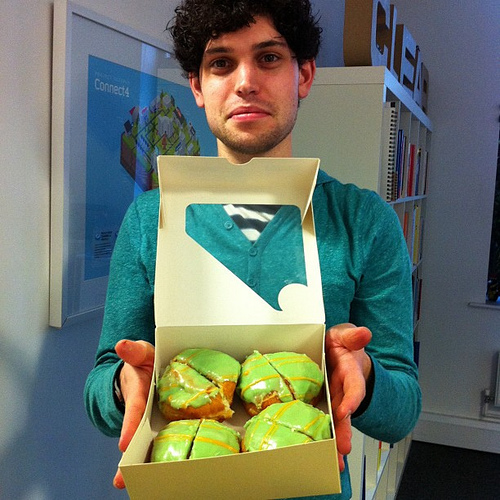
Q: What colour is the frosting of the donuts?
A: Green and yellow.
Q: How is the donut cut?
A: It is cut in half.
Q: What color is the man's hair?
A: Black.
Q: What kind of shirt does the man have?
A: A henley shirt.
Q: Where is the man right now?
A: In a room.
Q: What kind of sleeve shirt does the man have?
A: Long sleeve shirt.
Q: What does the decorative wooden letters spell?
A: CLEAR.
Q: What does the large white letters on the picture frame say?
A: Connect4.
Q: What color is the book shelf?
A: White.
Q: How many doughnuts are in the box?
A: Four.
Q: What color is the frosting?
A: Bright green and yellow.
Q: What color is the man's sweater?
A: Blue.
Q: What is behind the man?
A: White bookshelf.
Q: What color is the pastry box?
A: White.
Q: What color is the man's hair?
A: Black.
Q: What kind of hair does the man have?
A: Curly.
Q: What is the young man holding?
A: White box.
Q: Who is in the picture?
A: A man.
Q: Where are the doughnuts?
A: In a box.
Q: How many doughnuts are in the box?
A: 4.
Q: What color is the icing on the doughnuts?
A: Green.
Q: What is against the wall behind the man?
A: A shelf.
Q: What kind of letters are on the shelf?
A: Wooden.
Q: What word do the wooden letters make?
A: Clear.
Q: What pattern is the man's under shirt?
A: Stripes.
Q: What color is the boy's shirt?
A: Blue.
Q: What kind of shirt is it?
A: Cardigan.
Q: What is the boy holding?
A: Donuts.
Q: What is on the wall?
A: Pictures.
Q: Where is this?
A: Living room.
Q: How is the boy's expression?
A: Smile.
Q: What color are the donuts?
A: Green.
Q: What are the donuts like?
A: Sliced.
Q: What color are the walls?
A: White.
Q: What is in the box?
A: Donuts.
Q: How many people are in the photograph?
A: One.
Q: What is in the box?
A: Donuts.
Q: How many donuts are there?
A: Four.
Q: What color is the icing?
A: Green and yellow.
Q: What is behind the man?
A: A bookcase.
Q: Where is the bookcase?
A: Behind the man.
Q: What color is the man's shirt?
A: Blue.